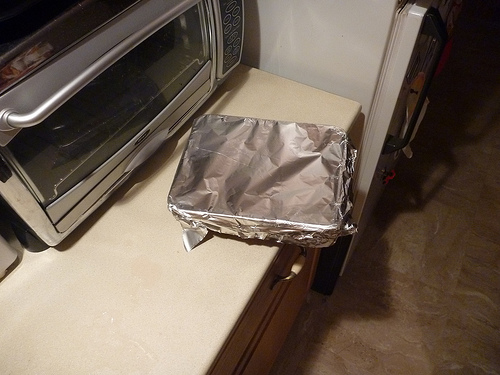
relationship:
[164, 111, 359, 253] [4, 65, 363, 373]
aluminum foil sitting on counter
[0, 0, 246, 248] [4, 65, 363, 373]
appliance sitting on counter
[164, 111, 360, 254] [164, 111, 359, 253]
aluminum foil covering aluminum foil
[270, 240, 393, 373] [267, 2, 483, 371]
shadow casted on floor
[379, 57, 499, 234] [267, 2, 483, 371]
shadow casted on floor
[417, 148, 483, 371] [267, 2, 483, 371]
shadow casted on floor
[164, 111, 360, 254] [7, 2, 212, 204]
aluminum foil reflected in glass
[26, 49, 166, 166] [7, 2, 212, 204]
reflection appearing in glass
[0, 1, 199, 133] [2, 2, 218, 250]
door handle mounted on door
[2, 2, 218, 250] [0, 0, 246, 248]
door attached to appliance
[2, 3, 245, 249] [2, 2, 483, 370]
appliance standing inside kitchen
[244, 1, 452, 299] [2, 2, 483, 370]
appliance standing inside kitchen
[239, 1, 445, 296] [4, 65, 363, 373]
appliance standing next to counter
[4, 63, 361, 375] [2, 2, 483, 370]
counter built into kitchen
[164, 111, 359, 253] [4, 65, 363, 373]
aluminum foil sitting on top of counter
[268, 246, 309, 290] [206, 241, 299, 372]
drawer pull mounted on cabinet drawer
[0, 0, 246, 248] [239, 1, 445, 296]
appliance standing next to appliance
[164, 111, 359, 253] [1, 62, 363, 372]
aluminum foil sitting on top of countertop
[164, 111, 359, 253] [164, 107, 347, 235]
aluminum foil covered in aluminum foil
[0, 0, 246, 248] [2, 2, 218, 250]
appliance with door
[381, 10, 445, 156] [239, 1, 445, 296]
handle of a appliance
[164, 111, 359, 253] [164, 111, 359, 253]
aluminum foil covered in aluminum foil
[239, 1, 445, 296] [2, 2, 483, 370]
appliance in kitchen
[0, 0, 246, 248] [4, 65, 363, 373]
appliance rests on counter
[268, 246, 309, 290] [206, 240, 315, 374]
drawer pull attached to cabinet drawer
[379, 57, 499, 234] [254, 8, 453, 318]
shadow cast by refridgerator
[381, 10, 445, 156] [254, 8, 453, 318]
handle attached to refridgerator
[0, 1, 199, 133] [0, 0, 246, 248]
door handle attached to appliance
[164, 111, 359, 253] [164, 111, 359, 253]
aluminum foil covered aluminum foil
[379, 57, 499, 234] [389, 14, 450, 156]
shadow of handles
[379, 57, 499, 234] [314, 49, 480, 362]
shadow on floor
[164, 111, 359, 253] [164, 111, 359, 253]
aluminum foil on a aluminum foil